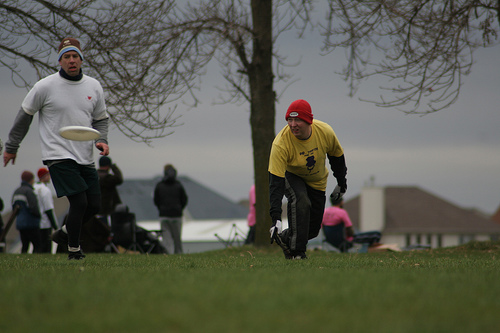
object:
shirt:
[267, 119, 343, 192]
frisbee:
[58, 126, 102, 142]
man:
[2, 38, 109, 259]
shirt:
[22, 72, 109, 166]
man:
[267, 99, 347, 260]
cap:
[285, 98, 314, 124]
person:
[318, 192, 353, 246]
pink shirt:
[321, 206, 357, 242]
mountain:
[235, 198, 292, 220]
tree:
[0, 0, 499, 250]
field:
[0, 240, 499, 333]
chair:
[110, 211, 148, 255]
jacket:
[153, 179, 187, 216]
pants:
[278, 170, 327, 254]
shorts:
[48, 162, 103, 198]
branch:
[393, 61, 461, 116]